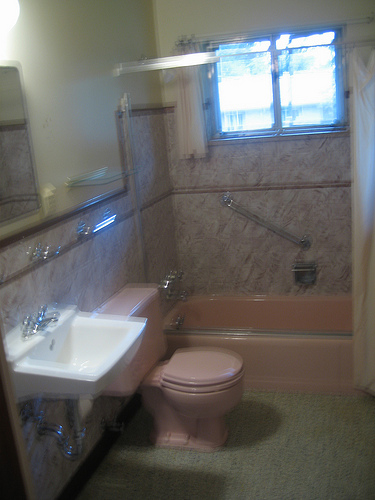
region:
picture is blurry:
[1, 3, 370, 496]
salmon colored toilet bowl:
[91, 279, 252, 456]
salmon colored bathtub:
[167, 292, 365, 361]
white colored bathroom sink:
[1, 295, 148, 402]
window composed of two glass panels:
[189, 24, 354, 145]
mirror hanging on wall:
[0, 64, 44, 227]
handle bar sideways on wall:
[218, 188, 315, 290]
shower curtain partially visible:
[343, 38, 373, 391]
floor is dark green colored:
[251, 390, 368, 490]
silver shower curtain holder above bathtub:
[105, 27, 369, 80]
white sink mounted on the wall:
[0, 290, 150, 413]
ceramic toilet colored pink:
[88, 276, 264, 465]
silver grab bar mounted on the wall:
[219, 190, 312, 256]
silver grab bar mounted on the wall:
[71, 205, 117, 239]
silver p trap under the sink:
[29, 392, 92, 469]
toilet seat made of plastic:
[156, 343, 247, 392]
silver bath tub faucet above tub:
[158, 266, 189, 307]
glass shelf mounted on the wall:
[60, 162, 145, 195]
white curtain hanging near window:
[162, 33, 211, 168]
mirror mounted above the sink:
[0, 54, 54, 239]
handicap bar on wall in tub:
[219, 190, 319, 257]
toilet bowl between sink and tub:
[80, 274, 251, 462]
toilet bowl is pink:
[75, 269, 258, 461]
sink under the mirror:
[2, 299, 145, 427]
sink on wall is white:
[1, 289, 157, 418]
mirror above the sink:
[1, 57, 51, 225]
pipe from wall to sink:
[29, 388, 91, 464]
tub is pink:
[153, 270, 374, 391]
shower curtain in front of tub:
[338, 34, 374, 403]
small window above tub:
[187, 17, 347, 149]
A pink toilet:
[90, 286, 243, 450]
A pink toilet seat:
[164, 346, 242, 384]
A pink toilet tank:
[90, 283, 167, 396]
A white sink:
[4, 303, 146, 400]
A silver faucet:
[21, 306, 58, 337]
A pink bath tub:
[161, 293, 351, 391]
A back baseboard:
[55, 388, 140, 497]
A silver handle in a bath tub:
[221, 192, 312, 248]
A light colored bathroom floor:
[76, 394, 371, 497]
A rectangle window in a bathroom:
[206, 29, 346, 136]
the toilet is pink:
[98, 279, 249, 472]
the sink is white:
[12, 299, 148, 413]